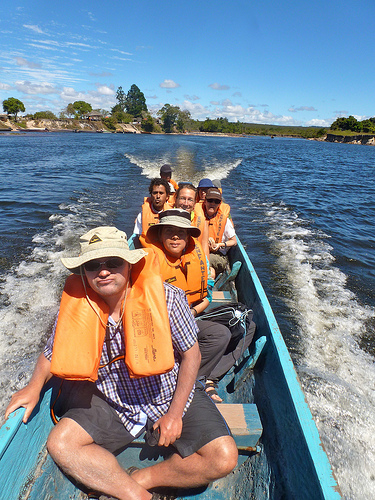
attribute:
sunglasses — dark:
[86, 260, 124, 273]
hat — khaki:
[59, 225, 150, 272]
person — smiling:
[174, 180, 199, 211]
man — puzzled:
[131, 177, 171, 241]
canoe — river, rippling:
[1, 134, 374, 450]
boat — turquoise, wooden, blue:
[1, 168, 343, 499]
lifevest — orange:
[48, 270, 177, 379]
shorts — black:
[61, 386, 233, 457]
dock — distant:
[14, 127, 52, 133]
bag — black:
[204, 312, 248, 355]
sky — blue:
[2, 0, 373, 123]